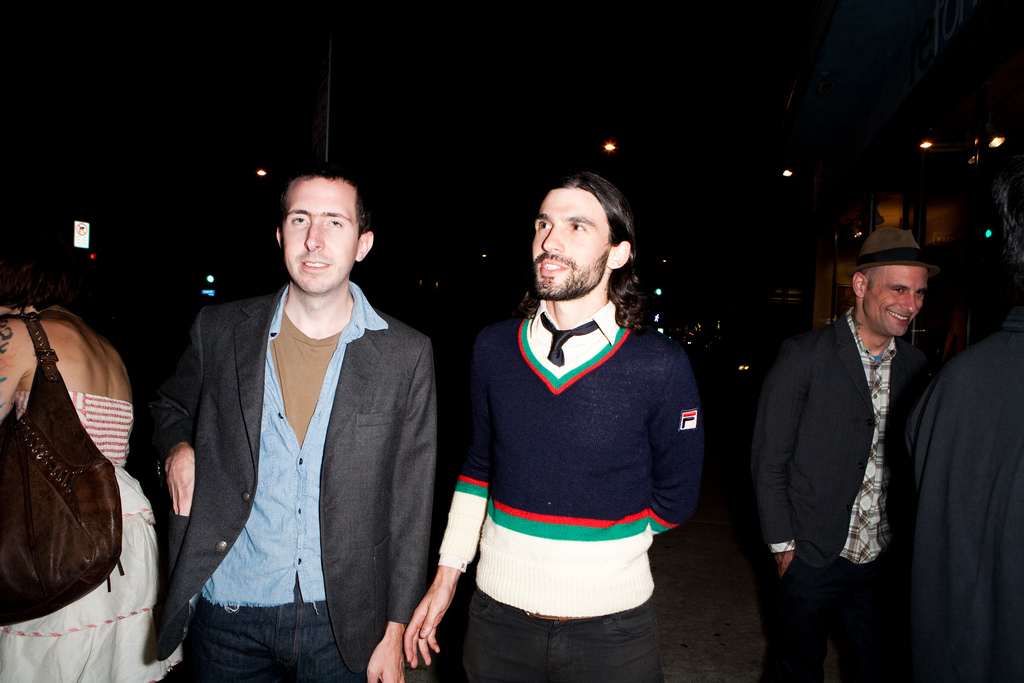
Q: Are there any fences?
A: No, there are no fences.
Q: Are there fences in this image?
A: No, there are no fences.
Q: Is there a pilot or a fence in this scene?
A: No, there are no fences or pilots.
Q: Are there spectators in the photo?
A: No, there are no spectators.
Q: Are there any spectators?
A: No, there are no spectators.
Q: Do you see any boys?
A: No, there are no boys.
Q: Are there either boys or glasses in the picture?
A: No, there are no boys or glasses.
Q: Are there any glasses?
A: No, there are no glasses.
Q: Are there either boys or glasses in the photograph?
A: No, there are no glasses or boys.